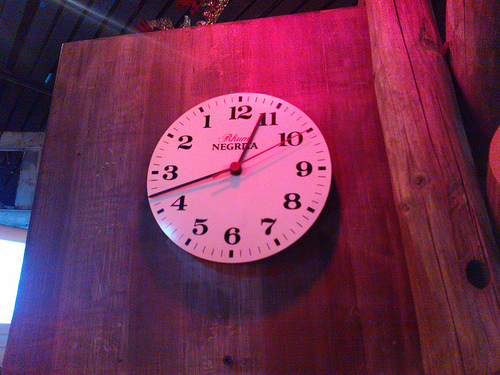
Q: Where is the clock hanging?
A: On the wall.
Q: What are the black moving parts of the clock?
A: Hands.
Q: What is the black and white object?
A: Clock.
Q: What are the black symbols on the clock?
A: Numbers.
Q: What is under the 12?
A: Words.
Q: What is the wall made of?
A: Wood.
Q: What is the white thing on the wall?
A: Clock.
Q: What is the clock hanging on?
A: Wall.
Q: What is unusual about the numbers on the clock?
A: They are in reverse order.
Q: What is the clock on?
A: Wall.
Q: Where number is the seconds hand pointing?
A: Ten.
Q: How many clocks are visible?
A: One.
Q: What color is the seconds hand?
A: Red.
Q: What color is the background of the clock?
A: White.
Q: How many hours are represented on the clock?
A: Twelve.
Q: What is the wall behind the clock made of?
A: Wood.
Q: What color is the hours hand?
A: Black.